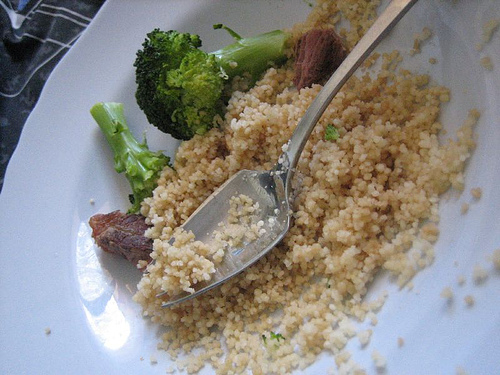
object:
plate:
[1, 2, 498, 373]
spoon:
[144, 0, 419, 308]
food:
[88, 209, 153, 271]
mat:
[0, 0, 106, 197]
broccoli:
[135, 23, 290, 141]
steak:
[294, 27, 345, 90]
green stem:
[91, 102, 132, 152]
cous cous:
[358, 328, 370, 347]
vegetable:
[89, 100, 177, 214]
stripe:
[21, 33, 74, 49]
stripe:
[26, 10, 90, 29]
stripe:
[40, 4, 93, 22]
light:
[74, 222, 131, 351]